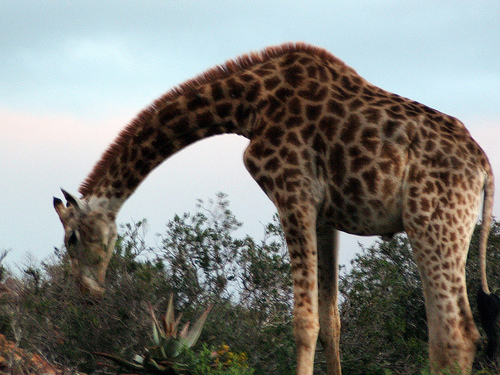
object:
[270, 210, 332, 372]
leg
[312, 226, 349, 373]
leg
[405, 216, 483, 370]
leg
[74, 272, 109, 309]
nose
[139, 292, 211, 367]
bunch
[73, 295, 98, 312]
foliage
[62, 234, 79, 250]
eye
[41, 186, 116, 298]
head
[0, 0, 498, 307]
sky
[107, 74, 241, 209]
neck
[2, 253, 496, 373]
land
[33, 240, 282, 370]
plants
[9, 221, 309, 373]
branches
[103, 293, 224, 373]
plant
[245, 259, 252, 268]
foilage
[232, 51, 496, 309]
body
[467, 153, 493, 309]
tail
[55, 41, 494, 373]
giraffe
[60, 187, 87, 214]
ear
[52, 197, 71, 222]
ear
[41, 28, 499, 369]
animal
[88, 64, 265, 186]
hair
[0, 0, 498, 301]
clouds